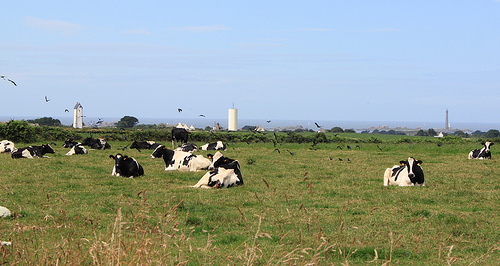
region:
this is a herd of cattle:
[5, 131, 254, 201]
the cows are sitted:
[111, 141, 243, 203]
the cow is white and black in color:
[378, 152, 425, 191]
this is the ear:
[398, 158, 405, 163]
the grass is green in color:
[303, 155, 345, 201]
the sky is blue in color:
[279, 18, 369, 96]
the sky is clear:
[285, 10, 380, 80]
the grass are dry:
[83, 217, 272, 264]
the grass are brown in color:
[219, 209, 324, 264]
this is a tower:
[224, 102, 240, 127]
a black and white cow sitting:
[7, 142, 55, 163]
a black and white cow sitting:
[67, 138, 89, 158]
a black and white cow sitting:
[111, 148, 142, 177]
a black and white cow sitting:
[129, 137, 160, 152]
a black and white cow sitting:
[150, 141, 208, 173]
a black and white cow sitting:
[194, 150, 245, 195]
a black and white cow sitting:
[198, 138, 228, 153]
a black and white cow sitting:
[385, 156, 425, 189]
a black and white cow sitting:
[465, 140, 492, 163]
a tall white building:
[72, 97, 83, 127]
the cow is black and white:
[178, 155, 195, 174]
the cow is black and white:
[165, 147, 215, 197]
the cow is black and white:
[182, 148, 201, 188]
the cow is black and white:
[181, 163, 190, 168]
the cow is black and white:
[184, 152, 192, 164]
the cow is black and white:
[179, 162, 188, 167]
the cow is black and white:
[179, 155, 192, 167]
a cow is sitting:
[381, 152, 455, 226]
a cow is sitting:
[394, 120, 466, 200]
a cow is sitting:
[365, 157, 422, 217]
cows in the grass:
[90, 110, 249, 225]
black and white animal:
[366, 146, 427, 204]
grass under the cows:
[281, 161, 336, 201]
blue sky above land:
[228, 23, 314, 67]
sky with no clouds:
[253, 30, 323, 64]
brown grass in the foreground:
[91, 196, 176, 260]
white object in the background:
[214, 87, 257, 139]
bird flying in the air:
[36, 86, 60, 115]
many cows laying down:
[52, 111, 245, 231]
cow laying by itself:
[365, 151, 425, 205]